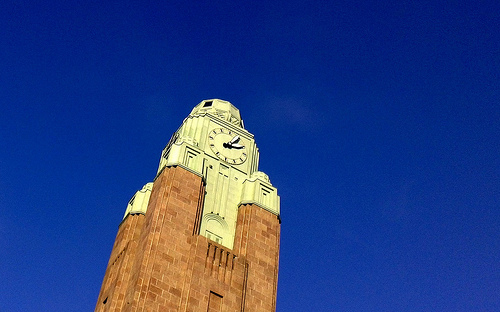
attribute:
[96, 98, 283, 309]
tower — brick, white, leaning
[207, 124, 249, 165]
clock — square, black, white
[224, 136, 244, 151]
hands — white, black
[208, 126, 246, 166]
numbers — roman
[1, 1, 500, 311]
sky — clear, blue, cloudless, deep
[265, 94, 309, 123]
clouds — white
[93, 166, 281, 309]
bricks — red